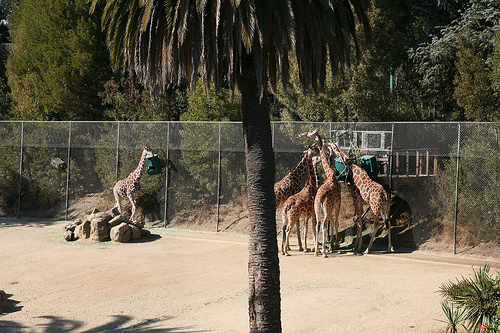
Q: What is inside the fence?
A: Giraffes.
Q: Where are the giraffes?
A: Inside the fence.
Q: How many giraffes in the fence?
A: Five.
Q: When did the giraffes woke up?
A: This morning.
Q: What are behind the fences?
A: Trees.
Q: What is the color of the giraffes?
A: Brown.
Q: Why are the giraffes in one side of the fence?
A: Eating.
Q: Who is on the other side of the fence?
A: No one.